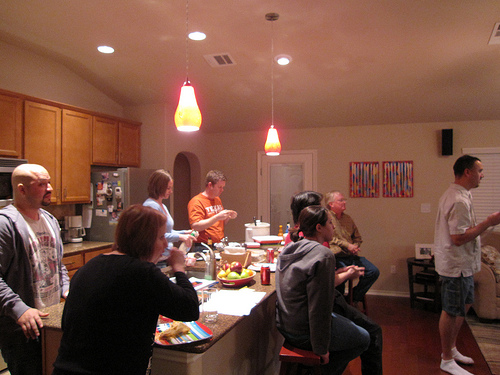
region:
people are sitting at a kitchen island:
[56, 193, 392, 371]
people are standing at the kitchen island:
[2, 152, 229, 332]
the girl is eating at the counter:
[59, 208, 203, 373]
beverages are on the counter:
[229, 205, 299, 307]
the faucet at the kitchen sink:
[188, 238, 218, 295]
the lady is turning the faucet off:
[148, 167, 217, 288]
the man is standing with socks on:
[433, 155, 499, 374]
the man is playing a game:
[438, 149, 499, 265]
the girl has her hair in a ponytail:
[284, 205, 339, 252]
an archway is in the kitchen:
[151, 131, 225, 262]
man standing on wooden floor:
[432, 151, 499, 373]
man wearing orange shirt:
[185, 171, 240, 249]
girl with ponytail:
[271, 204, 371, 374]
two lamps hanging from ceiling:
[172, 101, 294, 157]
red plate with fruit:
[210, 261, 258, 288]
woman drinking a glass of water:
[52, 202, 203, 373]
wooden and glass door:
[255, 150, 320, 234]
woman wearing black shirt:
[50, 204, 200, 374]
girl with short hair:
[141, 169, 197, 270]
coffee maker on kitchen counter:
[65, 213, 87, 244]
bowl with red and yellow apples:
[214, 259, 256, 293]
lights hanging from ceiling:
[168, 72, 285, 158]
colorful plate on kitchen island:
[155, 317, 215, 351]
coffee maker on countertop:
[63, 211, 89, 246]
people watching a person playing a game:
[273, 188, 387, 374]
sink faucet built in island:
[193, 239, 218, 282]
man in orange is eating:
[186, 167, 239, 244]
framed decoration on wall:
[346, 158, 418, 200]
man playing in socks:
[431, 150, 498, 373]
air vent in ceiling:
[205, 46, 237, 72]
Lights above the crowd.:
[162, 81, 348, 172]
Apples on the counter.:
[201, 245, 290, 304]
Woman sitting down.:
[267, 174, 423, 369]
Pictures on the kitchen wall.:
[339, 147, 441, 221]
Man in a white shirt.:
[420, 154, 474, 344]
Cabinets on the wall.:
[28, 88, 153, 246]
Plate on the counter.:
[153, 292, 236, 374]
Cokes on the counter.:
[223, 235, 314, 315]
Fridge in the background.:
[83, 160, 170, 237]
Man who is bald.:
[8, 144, 94, 219]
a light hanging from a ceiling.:
[163, 65, 210, 150]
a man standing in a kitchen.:
[427, 142, 498, 374]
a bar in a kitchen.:
[24, 242, 313, 373]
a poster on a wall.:
[377, 148, 419, 202]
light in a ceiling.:
[94, 34, 116, 62]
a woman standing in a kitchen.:
[134, 154, 189, 271]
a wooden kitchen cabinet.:
[52, 105, 101, 220]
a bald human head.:
[4, 151, 64, 216]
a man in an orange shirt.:
[181, 163, 238, 245]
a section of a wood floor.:
[399, 323, 424, 357]